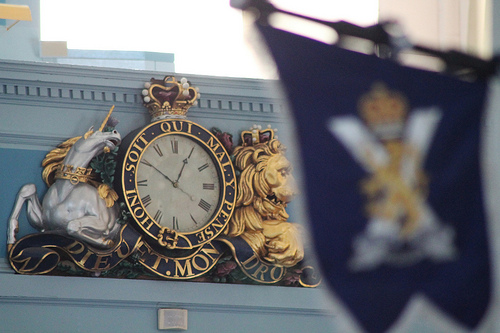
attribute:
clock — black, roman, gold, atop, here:
[148, 140, 202, 220]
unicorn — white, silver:
[61, 134, 117, 182]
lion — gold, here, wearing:
[235, 146, 295, 227]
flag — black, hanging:
[307, 75, 444, 244]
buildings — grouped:
[35, 31, 262, 151]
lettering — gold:
[120, 117, 217, 238]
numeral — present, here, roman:
[147, 135, 205, 176]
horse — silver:
[49, 149, 108, 228]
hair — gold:
[42, 159, 72, 192]